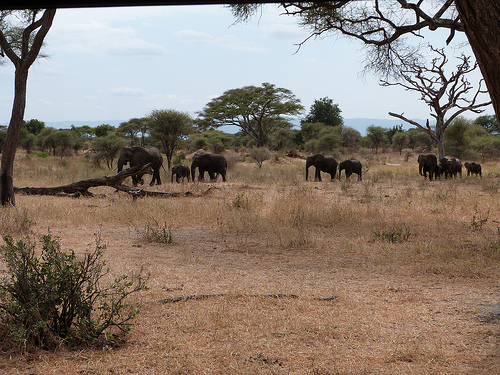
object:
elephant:
[112, 144, 168, 188]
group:
[411, 152, 486, 181]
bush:
[2, 223, 153, 357]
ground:
[282, 276, 499, 370]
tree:
[202, 82, 303, 148]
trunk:
[0, 0, 52, 211]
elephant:
[170, 162, 192, 184]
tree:
[385, 44, 492, 160]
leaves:
[380, 86, 385, 89]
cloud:
[58, 9, 164, 64]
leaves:
[289, 107, 292, 109]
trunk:
[14, 180, 98, 200]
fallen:
[19, 164, 219, 199]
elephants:
[338, 156, 364, 183]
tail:
[161, 162, 171, 179]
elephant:
[191, 150, 228, 183]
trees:
[147, 108, 197, 173]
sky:
[91, 23, 232, 63]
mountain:
[44, 120, 131, 136]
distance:
[334, 100, 402, 135]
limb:
[18, 163, 216, 199]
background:
[2, 4, 500, 129]